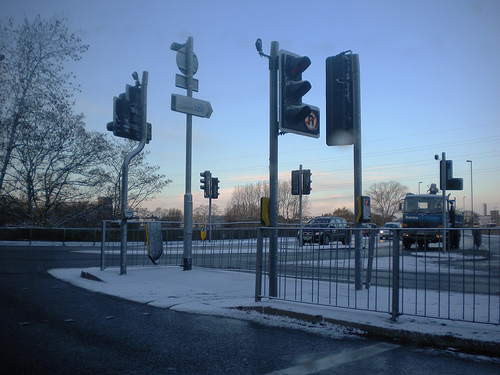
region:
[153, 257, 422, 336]
snow on the ground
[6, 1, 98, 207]
trees with leaves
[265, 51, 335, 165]
street light on a pole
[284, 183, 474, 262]
cars stopped at the light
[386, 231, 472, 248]
lights are turned on the truck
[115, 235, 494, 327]
walkway for walker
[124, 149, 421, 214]
long clouds in the sky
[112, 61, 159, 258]
the pole is curved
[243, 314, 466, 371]
line telling you to stop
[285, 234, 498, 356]
metal railings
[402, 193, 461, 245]
a blue truck on the side of the road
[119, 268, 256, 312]
a snow covered side walk at the intersection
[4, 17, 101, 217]
a tall bare tree across the street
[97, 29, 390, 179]
several signs and traffic signals at the intersection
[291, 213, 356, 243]
a black sedan driving down the road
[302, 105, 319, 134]
a sign with a round white circle with a black R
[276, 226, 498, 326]
a silver metal barricade along the road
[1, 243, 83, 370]
the road that is wet and ice covered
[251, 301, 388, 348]
a curb at the intersection with snow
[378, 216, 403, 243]
a car with it's headlights on in the road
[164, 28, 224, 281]
back view of street signs on pole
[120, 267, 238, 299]
white snow on the ground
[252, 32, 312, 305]
traffic light signals on a pole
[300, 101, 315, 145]
no turn on red sign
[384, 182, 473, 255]
blue truck on the street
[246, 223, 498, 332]
silver metal fence on the sidewalk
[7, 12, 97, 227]
bare trees along side of road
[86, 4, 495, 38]
blue sky in the background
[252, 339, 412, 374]
white painted line on the road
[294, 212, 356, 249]
black minivan on the road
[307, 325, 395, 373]
White painted line on road.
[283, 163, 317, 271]
Two traffic lights on a pole.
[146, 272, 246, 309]
White snow on ground.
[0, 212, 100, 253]
Rail on a street.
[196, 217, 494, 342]
Metal rail on a street.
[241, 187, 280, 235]
Black and yellow traffic sign on pole.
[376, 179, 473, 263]
Truck on a street.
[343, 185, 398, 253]
Sign on a pole.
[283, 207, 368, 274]
Car on a street.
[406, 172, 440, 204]
Equipment on top of truck.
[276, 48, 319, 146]
this is a traffic light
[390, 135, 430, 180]
this are wires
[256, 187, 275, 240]
this is a road reflection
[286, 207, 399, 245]
this are vehicles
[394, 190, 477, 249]
this is a truck on the road side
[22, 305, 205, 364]
this is the road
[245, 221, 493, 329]
this is a road side barrier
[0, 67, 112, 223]
these are trees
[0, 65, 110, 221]
the tree has branches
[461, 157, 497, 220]
these are street lights